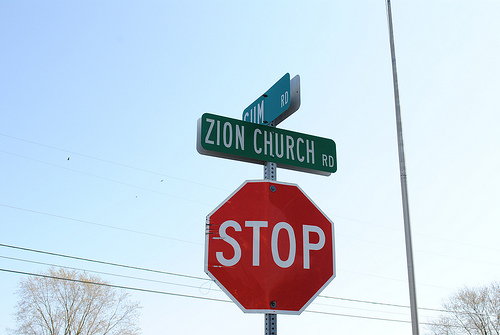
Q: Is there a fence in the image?
A: No, there are no fences.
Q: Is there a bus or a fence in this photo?
A: No, there are no fences or buses.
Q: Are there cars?
A: No, there are no cars.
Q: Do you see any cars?
A: No, there are no cars.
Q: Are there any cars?
A: No, there are no cars.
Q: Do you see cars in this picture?
A: No, there are no cars.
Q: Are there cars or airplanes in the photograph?
A: No, there are no cars or airplanes.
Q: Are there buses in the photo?
A: No, there are no buses.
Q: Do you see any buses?
A: No, there are no buses.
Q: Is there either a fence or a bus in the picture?
A: No, there are no buses or fences.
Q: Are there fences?
A: No, there are no fences.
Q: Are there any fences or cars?
A: No, there are no fences or cars.